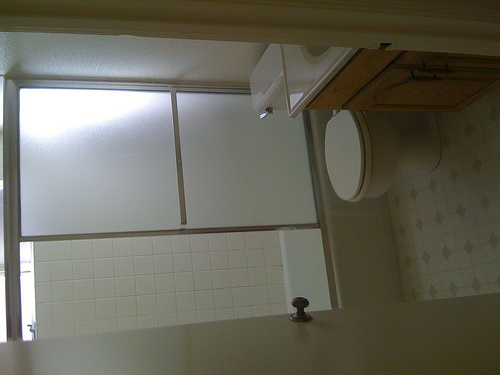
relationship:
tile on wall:
[30, 226, 296, 338] [78, 241, 319, 339]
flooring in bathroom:
[336, 93, 499, 302] [1, 27, 499, 338]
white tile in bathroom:
[86, 260, 269, 321] [215, 125, 406, 225]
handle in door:
[289, 297, 314, 323] [4, 294, 497, 367]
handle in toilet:
[250, 105, 277, 124] [245, 43, 447, 205]